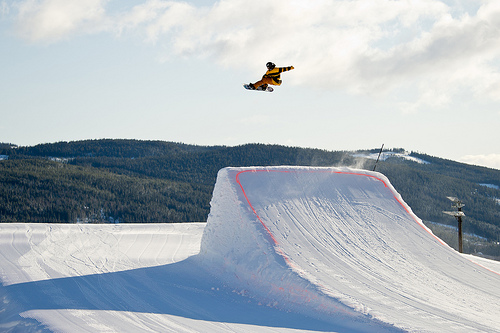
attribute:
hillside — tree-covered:
[2, 138, 499, 259]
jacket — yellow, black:
[260, 69, 287, 86]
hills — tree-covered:
[98, 138, 218, 212]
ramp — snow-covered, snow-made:
[195, 163, 498, 332]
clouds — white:
[3, 5, 497, 60]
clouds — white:
[41, 10, 498, 81]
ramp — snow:
[224, 167, 499, 332]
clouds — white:
[3, 0, 498, 114]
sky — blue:
[3, 0, 499, 168]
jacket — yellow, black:
[246, 61, 296, 81]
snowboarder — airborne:
[246, 63, 291, 92]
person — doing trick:
[248, 62, 295, 95]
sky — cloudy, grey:
[16, 4, 176, 100]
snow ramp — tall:
[191, 160, 497, 327]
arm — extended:
[277, 64, 294, 73]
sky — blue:
[10, 52, 100, 92]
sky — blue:
[9, 47, 107, 79]